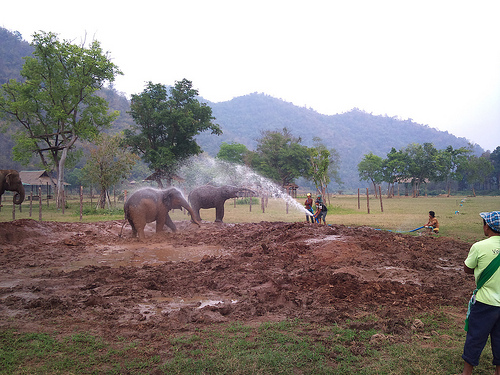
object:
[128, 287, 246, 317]
mud puddle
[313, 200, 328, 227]
dudes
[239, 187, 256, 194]
trunk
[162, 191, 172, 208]
ear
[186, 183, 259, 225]
elephant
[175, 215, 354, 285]
mud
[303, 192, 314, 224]
man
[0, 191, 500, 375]
ground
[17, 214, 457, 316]
mud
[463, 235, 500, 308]
shirt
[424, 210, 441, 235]
person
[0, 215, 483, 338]
dirt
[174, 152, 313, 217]
water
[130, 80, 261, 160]
mountains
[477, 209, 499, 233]
blue hat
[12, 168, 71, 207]
building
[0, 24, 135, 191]
mountains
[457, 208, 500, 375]
guy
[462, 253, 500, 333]
bag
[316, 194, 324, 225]
guy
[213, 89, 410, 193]
mountains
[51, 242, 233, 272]
lake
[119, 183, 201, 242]
elephant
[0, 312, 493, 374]
grass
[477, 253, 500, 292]
strap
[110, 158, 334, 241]
festival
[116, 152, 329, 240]
bath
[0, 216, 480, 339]
muck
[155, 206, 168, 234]
legs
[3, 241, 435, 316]
pit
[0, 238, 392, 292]
mud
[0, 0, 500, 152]
sky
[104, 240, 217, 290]
mud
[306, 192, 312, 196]
hat